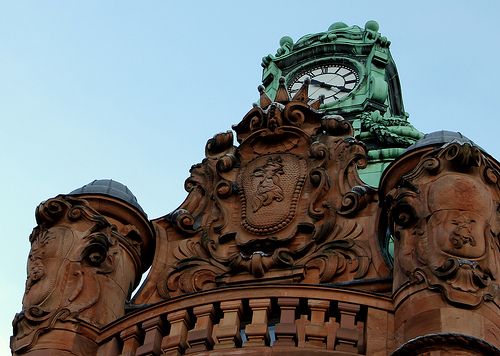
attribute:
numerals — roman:
[275, 49, 372, 108]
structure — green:
[244, 20, 440, 193]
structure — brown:
[7, 67, 499, 353]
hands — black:
[288, 61, 359, 108]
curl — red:
[165, 197, 230, 254]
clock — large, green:
[253, 9, 433, 180]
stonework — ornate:
[213, 137, 362, 340]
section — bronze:
[94, 140, 266, 350]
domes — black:
[93, 164, 103, 188]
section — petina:
[289, 22, 436, 157]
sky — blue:
[96, 73, 253, 213]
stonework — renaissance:
[194, 80, 494, 335]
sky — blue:
[149, 2, 243, 163]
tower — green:
[275, 43, 373, 94]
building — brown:
[237, 118, 387, 299]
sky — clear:
[42, 2, 175, 131]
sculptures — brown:
[205, 104, 351, 232]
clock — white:
[281, 40, 367, 119]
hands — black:
[316, 63, 338, 98]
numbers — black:
[311, 54, 346, 94]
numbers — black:
[302, 39, 345, 81]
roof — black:
[78, 160, 129, 195]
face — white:
[251, 50, 351, 109]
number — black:
[319, 71, 343, 81]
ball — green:
[339, 19, 347, 24]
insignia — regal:
[207, 153, 316, 243]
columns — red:
[262, 240, 310, 340]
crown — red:
[272, 93, 322, 108]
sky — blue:
[85, 43, 209, 119]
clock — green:
[346, 119, 406, 149]